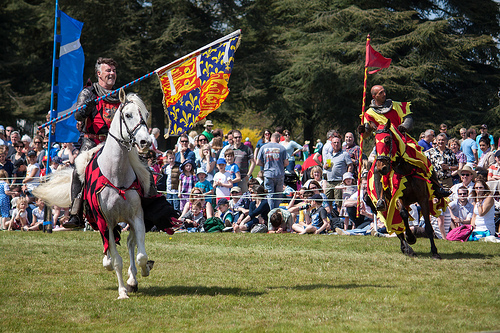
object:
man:
[62, 57, 185, 228]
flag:
[156, 29, 244, 139]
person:
[322, 137, 354, 219]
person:
[228, 129, 257, 193]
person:
[425, 133, 459, 189]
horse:
[32, 87, 160, 301]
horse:
[362, 118, 453, 259]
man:
[356, 85, 452, 211]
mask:
[368, 118, 401, 175]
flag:
[365, 42, 392, 74]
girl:
[213, 157, 233, 204]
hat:
[216, 157, 227, 164]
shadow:
[103, 284, 400, 297]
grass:
[0, 228, 499, 330]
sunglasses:
[234, 136, 241, 138]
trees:
[268, 2, 493, 149]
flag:
[49, 10, 86, 143]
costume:
[358, 101, 435, 173]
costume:
[74, 83, 124, 145]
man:
[256, 133, 289, 210]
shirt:
[257, 142, 287, 179]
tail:
[29, 167, 77, 208]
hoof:
[126, 278, 139, 293]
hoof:
[146, 260, 154, 269]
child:
[334, 172, 360, 231]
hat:
[343, 172, 355, 184]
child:
[214, 198, 233, 232]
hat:
[229, 186, 241, 193]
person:
[448, 165, 477, 203]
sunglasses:
[461, 173, 469, 176]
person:
[446, 185, 475, 236]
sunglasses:
[458, 193, 467, 196]